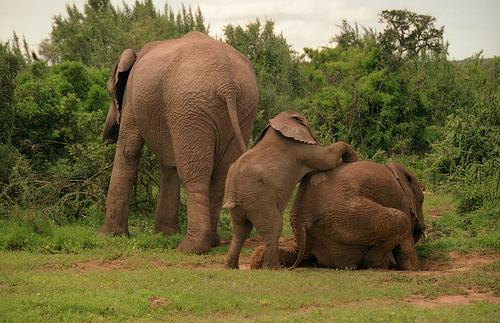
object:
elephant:
[251, 158, 428, 270]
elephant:
[220, 109, 360, 269]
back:
[318, 170, 373, 193]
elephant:
[100, 30, 260, 255]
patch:
[429, 292, 464, 301]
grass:
[3, 266, 163, 321]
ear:
[271, 115, 316, 145]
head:
[270, 110, 319, 143]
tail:
[223, 95, 246, 154]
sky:
[450, 0, 500, 40]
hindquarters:
[171, 79, 262, 183]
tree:
[376, 5, 453, 60]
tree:
[39, 0, 117, 65]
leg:
[248, 207, 284, 270]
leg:
[224, 208, 253, 268]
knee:
[381, 205, 414, 242]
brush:
[346, 72, 428, 121]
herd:
[100, 25, 430, 273]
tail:
[223, 161, 238, 211]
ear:
[102, 48, 136, 144]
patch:
[447, 255, 476, 266]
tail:
[287, 224, 311, 271]